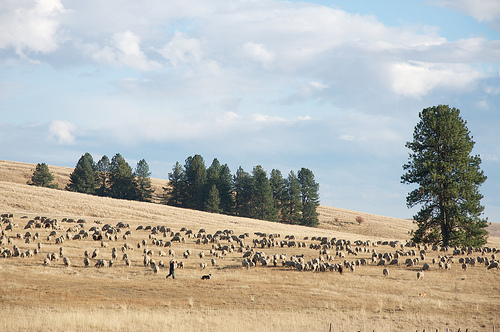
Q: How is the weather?
A: Sunny.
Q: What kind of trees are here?
A: Pine.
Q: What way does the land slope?
A: Up toward the left.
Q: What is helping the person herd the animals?
A: A dog.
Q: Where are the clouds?
A: In the sky.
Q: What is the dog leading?
A: The person.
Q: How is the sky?
A: Cloudy.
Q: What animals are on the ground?
A: Birds.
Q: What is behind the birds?
A: A row of trees.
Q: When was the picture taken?
A: During the daytime.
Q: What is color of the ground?
A: Tan.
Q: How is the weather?
A: Sunny and warm.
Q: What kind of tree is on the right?
A: A pine tree.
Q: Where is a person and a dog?
A: In front of the birds.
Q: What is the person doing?
A: Running.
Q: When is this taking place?
A: Daytime.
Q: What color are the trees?
A: Green.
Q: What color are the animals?
A: Brown.